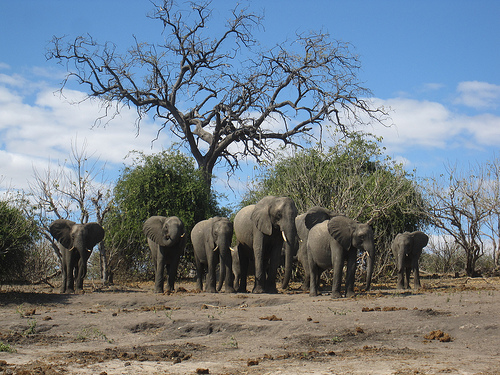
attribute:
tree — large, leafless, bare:
[41, 0, 400, 215]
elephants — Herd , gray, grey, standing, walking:
[45, 193, 432, 298]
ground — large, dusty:
[0, 274, 499, 374]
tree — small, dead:
[398, 155, 500, 278]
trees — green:
[0, 141, 436, 283]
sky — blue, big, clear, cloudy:
[0, 0, 499, 271]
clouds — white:
[1, 57, 500, 256]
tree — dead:
[27, 130, 106, 270]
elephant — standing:
[42, 208, 108, 296]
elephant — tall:
[228, 188, 304, 297]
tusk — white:
[277, 227, 289, 245]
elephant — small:
[388, 225, 426, 291]